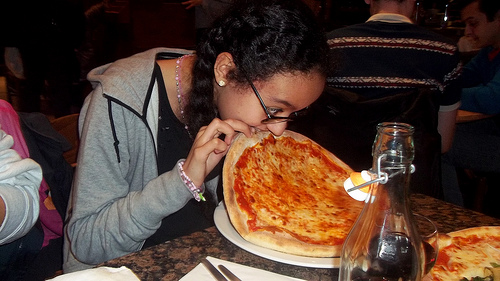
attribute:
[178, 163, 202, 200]
bracelet — pink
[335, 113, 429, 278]
bottle — on the table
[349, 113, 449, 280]
bottle — glass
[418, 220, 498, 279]
pizza — cooked, cheese, uncut, baked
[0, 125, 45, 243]
sweater — white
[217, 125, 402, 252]
uncut pizza — cheese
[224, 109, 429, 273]
pizza — uncut, cooked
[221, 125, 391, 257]
pizza — cooked, uncut, cheese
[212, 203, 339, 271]
plate — white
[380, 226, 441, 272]
glass — on the table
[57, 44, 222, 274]
sweater — gray